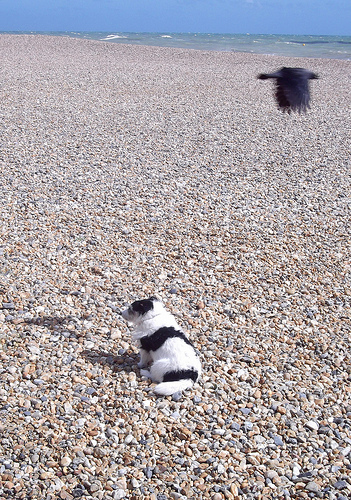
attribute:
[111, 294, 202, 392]
dog — black, white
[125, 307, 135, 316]
dog's eye — black, white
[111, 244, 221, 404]
dog — white, black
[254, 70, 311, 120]
bird — in motion/aloft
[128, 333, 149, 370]
arm — white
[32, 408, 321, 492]
pebbles — brown, grey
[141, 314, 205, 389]
dog's back — dogs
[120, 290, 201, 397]
dog — black, black and white, white, sitting/relaxed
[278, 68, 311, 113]
wings — black